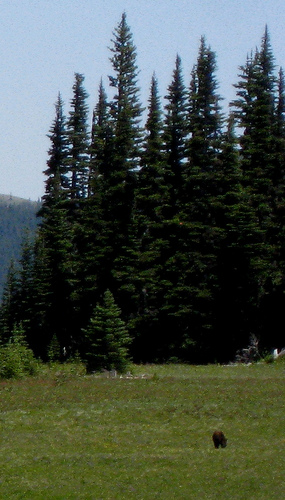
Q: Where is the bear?
A: On the grass.